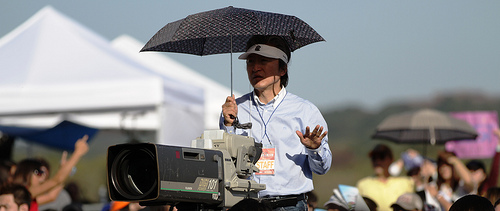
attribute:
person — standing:
[220, 37, 332, 210]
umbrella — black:
[138, 6, 327, 124]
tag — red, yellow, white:
[250, 83, 288, 174]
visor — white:
[238, 43, 291, 66]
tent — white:
[0, 6, 249, 151]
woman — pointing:
[11, 134, 91, 210]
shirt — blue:
[219, 87, 332, 197]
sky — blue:
[0, 1, 499, 115]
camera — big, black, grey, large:
[108, 129, 266, 210]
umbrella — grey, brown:
[369, 107, 479, 162]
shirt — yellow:
[357, 175, 414, 210]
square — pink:
[441, 110, 500, 158]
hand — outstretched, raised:
[295, 124, 329, 148]